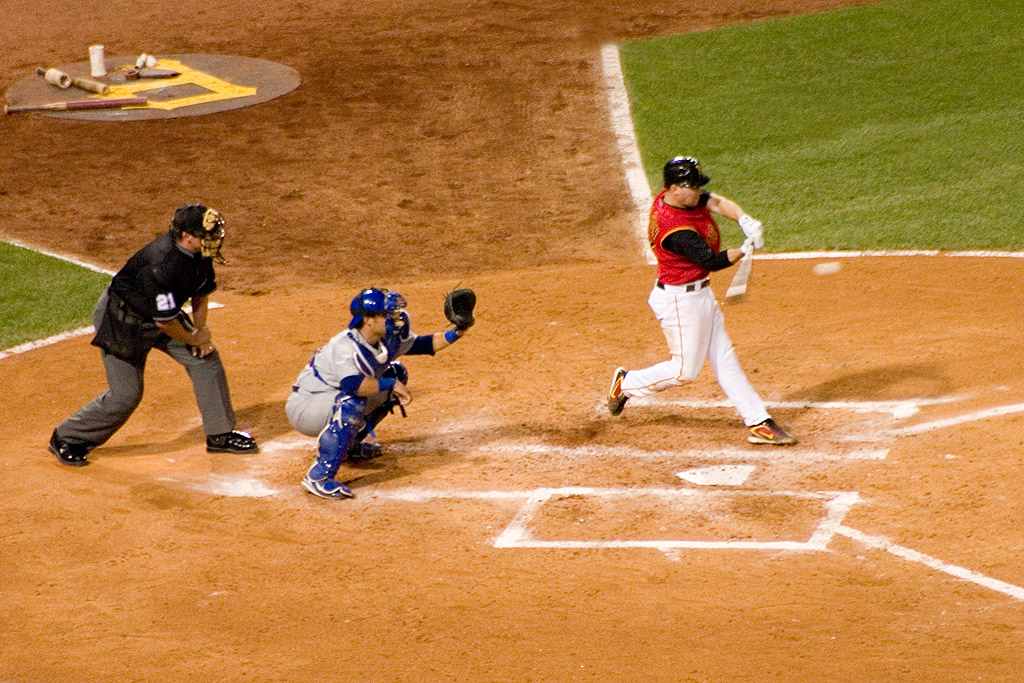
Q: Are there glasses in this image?
A: No, there are no glasses.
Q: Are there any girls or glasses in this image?
A: No, there are no glasses or girls.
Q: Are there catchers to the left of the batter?
A: Yes, there is a catcher to the left of the batter.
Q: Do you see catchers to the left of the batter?
A: Yes, there is a catcher to the left of the batter.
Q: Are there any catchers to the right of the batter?
A: No, the catcher is to the left of the batter.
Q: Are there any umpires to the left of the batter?
A: No, there is a catcher to the left of the batter.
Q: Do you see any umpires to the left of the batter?
A: No, there is a catcher to the left of the batter.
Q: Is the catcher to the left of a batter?
A: Yes, the catcher is to the left of a batter.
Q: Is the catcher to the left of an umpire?
A: No, the catcher is to the left of a batter.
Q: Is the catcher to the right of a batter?
A: No, the catcher is to the left of a batter.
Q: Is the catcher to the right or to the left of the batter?
A: The catcher is to the left of the batter.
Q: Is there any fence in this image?
A: No, there are no fences.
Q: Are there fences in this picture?
A: No, there are no fences.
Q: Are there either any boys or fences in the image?
A: No, there are no fences or boys.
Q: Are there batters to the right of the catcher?
A: Yes, there is a batter to the right of the catcher.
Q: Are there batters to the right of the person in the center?
A: Yes, there is a batter to the right of the catcher.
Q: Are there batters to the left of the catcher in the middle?
A: No, the batter is to the right of the catcher.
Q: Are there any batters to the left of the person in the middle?
A: No, the batter is to the right of the catcher.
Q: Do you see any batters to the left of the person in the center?
A: No, the batter is to the right of the catcher.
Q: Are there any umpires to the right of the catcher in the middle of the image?
A: No, there is a batter to the right of the catcher.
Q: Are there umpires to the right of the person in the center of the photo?
A: No, there is a batter to the right of the catcher.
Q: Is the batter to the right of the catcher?
A: Yes, the batter is to the right of the catcher.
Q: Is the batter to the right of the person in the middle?
A: Yes, the batter is to the right of the catcher.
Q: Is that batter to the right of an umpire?
A: No, the batter is to the right of the catcher.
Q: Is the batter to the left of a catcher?
A: No, the batter is to the right of a catcher.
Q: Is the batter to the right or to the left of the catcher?
A: The batter is to the right of the catcher.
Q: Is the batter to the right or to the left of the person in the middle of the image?
A: The batter is to the right of the catcher.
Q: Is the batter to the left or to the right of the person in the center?
A: The batter is to the right of the catcher.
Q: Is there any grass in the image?
A: Yes, there is grass.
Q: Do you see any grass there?
A: Yes, there is grass.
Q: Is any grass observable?
A: Yes, there is grass.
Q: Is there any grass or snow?
A: Yes, there is grass.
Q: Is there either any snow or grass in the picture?
A: Yes, there is grass.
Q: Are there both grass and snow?
A: No, there is grass but no snow.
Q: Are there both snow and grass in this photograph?
A: No, there is grass but no snow.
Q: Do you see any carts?
A: No, there are no carts.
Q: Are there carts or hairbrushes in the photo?
A: No, there are no carts or hairbrushes.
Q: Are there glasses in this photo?
A: No, there are no glasses.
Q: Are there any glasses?
A: No, there are no glasses.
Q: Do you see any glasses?
A: No, there are no glasses.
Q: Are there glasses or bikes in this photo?
A: No, there are no glasses or bikes.